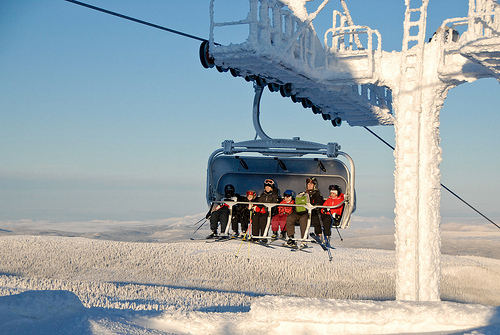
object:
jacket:
[319, 192, 347, 216]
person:
[283, 174, 323, 249]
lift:
[202, 136, 358, 242]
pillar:
[389, 83, 448, 304]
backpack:
[294, 191, 310, 213]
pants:
[269, 214, 289, 239]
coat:
[256, 189, 281, 212]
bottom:
[250, 209, 270, 239]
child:
[230, 189, 258, 241]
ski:
[232, 231, 275, 249]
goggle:
[246, 191, 254, 196]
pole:
[329, 210, 345, 243]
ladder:
[394, 0, 430, 303]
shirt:
[214, 195, 238, 211]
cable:
[67, 0, 224, 47]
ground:
[0, 300, 500, 334]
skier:
[285, 172, 319, 248]